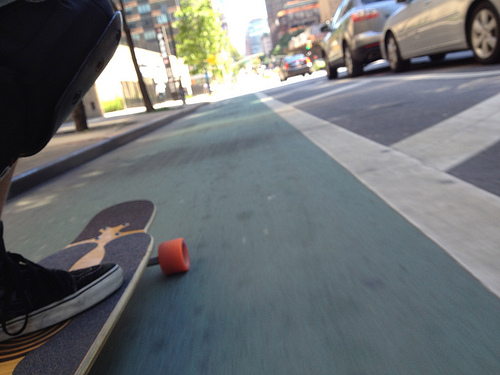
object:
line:
[389, 95, 500, 171]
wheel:
[158, 237, 191, 276]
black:
[10, 200, 155, 373]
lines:
[251, 93, 500, 299]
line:
[288, 80, 365, 108]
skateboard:
[0, 199, 190, 375]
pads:
[0, 0, 123, 160]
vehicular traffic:
[380, 0, 500, 74]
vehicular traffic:
[316, 0, 407, 80]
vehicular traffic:
[276, 53, 313, 82]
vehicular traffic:
[0, 0, 188, 374]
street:
[1, 72, 498, 372]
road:
[3, 77, 499, 373]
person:
[0, 0, 123, 343]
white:
[330, 143, 454, 155]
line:
[372, 69, 500, 82]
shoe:
[0, 248, 124, 341]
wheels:
[467, 5, 500, 66]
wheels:
[385, 31, 412, 73]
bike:
[179, 80, 186, 104]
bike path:
[2, 94, 498, 374]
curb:
[5, 103, 193, 200]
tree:
[170, 1, 224, 96]